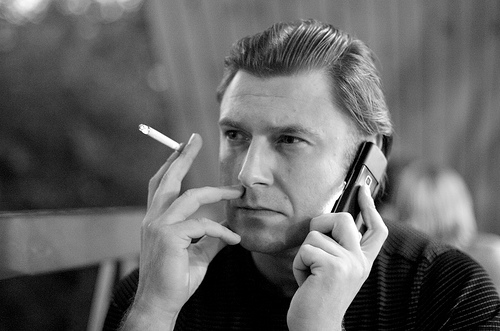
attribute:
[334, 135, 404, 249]
phone — cell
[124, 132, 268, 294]
hand — man's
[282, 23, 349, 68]
marks — comb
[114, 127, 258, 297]
hand — man's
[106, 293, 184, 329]
wrist — man's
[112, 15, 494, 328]
man — talking, holding, smiling, thoughtful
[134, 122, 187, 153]
cigarrate — white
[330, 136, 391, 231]
mobile — grey, back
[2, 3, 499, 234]
background — white, out-of-focus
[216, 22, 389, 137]
hair — gray, black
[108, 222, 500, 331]
shirt — dark, striped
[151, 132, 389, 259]
finger — bent, man's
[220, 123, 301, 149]
eye — dark